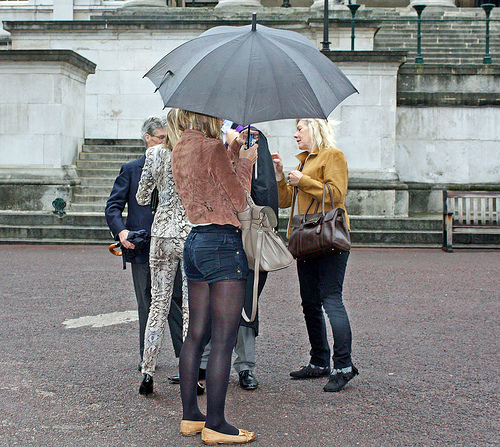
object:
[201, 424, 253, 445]
shoe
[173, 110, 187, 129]
hair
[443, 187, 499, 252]
bench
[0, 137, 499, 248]
stairway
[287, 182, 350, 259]
purse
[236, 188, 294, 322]
handbag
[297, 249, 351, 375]
pants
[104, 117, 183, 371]
man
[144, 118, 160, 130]
grey hair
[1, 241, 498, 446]
ground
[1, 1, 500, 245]
building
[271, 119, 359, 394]
woman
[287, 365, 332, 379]
right foot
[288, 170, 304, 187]
left hand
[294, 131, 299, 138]
nose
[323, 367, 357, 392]
left foot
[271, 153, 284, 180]
right hand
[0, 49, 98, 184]
wall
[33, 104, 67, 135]
brick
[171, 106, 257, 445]
person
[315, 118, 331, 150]
hair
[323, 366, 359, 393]
shoe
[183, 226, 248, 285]
shorts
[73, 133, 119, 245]
part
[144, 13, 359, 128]
part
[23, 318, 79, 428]
part